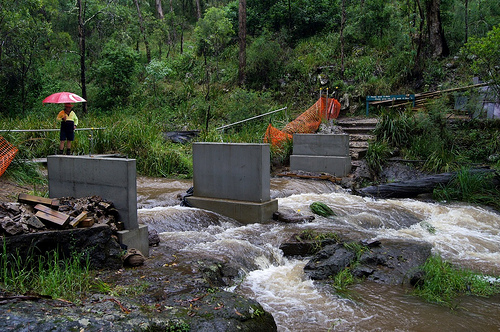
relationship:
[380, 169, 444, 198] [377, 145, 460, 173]
log on ground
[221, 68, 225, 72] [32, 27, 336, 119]
leaves in trees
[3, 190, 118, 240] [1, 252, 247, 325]
board on ground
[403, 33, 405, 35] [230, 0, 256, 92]
leave are on tree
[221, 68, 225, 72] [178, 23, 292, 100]
leaves are on trees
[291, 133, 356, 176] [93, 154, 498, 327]
support across stream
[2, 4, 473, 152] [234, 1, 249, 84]
slope of tree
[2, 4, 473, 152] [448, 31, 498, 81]
slope of bush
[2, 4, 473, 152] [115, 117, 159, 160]
slope of plant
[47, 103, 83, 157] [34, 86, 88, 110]
person holding an umbrella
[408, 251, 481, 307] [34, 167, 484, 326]
grass in water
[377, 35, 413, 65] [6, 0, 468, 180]
leave in tree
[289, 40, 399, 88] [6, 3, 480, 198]
leaves in trees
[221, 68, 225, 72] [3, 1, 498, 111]
leaves in trees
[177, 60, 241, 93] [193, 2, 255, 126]
leaves in trees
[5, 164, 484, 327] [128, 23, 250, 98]
stream through vegetation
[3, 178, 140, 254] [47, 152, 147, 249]
debris against support